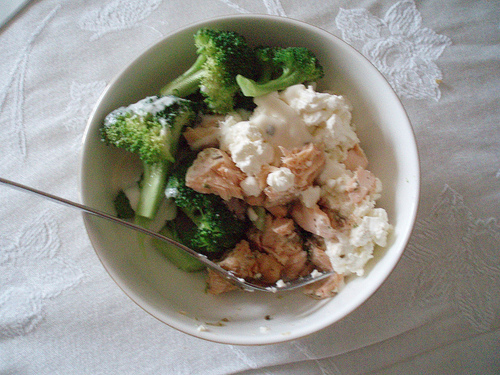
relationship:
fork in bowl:
[0, 176, 333, 293] [76, 12, 422, 347]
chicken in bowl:
[191, 159, 241, 194] [76, 12, 422, 347]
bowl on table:
[76, 12, 422, 347] [392, 33, 492, 183]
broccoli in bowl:
[113, 101, 179, 187] [76, 12, 422, 347]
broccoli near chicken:
[113, 101, 179, 187] [191, 159, 241, 194]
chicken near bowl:
[191, 159, 241, 194] [76, 12, 422, 347]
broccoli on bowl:
[113, 101, 179, 187] [76, 12, 422, 347]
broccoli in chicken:
[113, 101, 179, 187] [191, 159, 241, 194]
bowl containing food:
[76, 12, 424, 347] [100, 24, 395, 301]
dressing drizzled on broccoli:
[101, 97, 191, 124] [113, 101, 179, 187]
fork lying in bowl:
[2, 176, 332, 296] [76, 12, 424, 347]